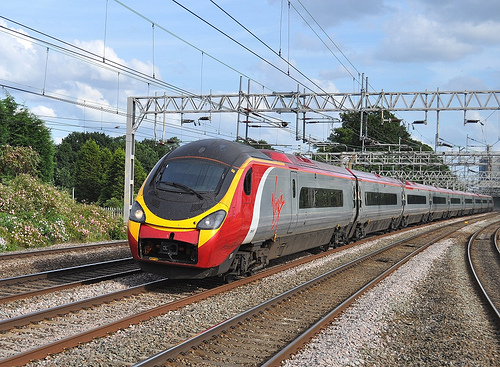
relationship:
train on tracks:
[129, 140, 492, 287] [0, 278, 210, 363]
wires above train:
[1, 1, 439, 171] [129, 140, 492, 287]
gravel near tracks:
[4, 208, 495, 365] [0, 278, 210, 363]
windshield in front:
[146, 154, 241, 220] [128, 140, 278, 273]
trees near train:
[3, 96, 188, 221] [129, 140, 492, 287]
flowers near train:
[0, 145, 131, 242] [129, 140, 492, 287]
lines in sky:
[1, 1, 439, 171] [3, 1, 498, 197]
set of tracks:
[2, 208, 495, 365] [0, 278, 210, 363]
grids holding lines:
[126, 92, 496, 120] [1, 1, 439, 171]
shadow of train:
[34, 246, 234, 291] [129, 140, 492, 287]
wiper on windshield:
[152, 177, 205, 200] [146, 154, 241, 220]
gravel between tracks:
[4, 208, 495, 365] [0, 278, 210, 363]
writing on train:
[270, 174, 285, 227] [129, 140, 492, 287]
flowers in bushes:
[0, 145, 131, 242] [2, 145, 127, 248]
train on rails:
[129, 140, 492, 287] [2, 212, 498, 362]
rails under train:
[2, 212, 498, 362] [129, 140, 492, 287]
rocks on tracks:
[4, 208, 495, 365] [0, 278, 210, 363]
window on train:
[294, 184, 345, 206] [129, 140, 492, 287]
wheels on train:
[230, 246, 266, 274] [129, 140, 492, 287]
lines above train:
[1, 1, 439, 171] [129, 140, 492, 287]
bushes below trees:
[2, 145, 127, 248] [3, 96, 188, 221]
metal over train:
[128, 86, 499, 195] [129, 140, 492, 287]